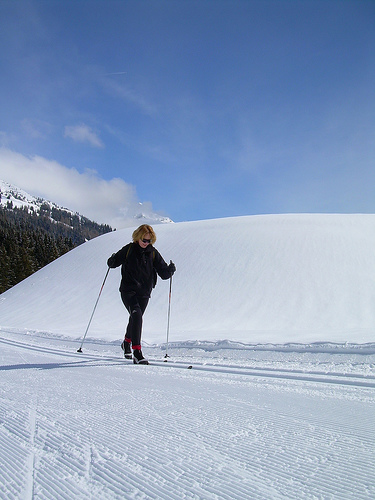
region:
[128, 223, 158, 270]
woman is wearing sunglasses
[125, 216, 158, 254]
woman is wearing sunglasses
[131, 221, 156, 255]
woman is wearing sunglasses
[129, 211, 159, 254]
woman is wearing sunglasses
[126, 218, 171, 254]
woman is wearing sunglasses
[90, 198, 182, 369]
woman skiing in white snow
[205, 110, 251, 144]
white clouds in blue sky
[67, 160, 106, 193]
white clouds in blue sky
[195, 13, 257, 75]
white clouds in blue sky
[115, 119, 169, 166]
white clouds in blue sky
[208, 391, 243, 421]
white snow on ground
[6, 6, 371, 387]
blue sky with thin and puffy clouds over mountains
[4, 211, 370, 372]
mound of smooth snow behind skier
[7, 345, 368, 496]
narrow ridges along ski path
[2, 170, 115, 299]
snow capping mountain covered with trees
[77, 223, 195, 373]
skier looking down at skis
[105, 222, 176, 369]
skier wearing dark outfit with red cuff at ankle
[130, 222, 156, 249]
woman with brown hair parted in middle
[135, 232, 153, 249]
dark sunglasses over face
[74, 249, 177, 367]
ski poles placed to the side of body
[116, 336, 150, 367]
black ski boots with white trim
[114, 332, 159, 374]
the shoes are black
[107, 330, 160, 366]
the shoes are black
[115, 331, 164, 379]
the shoes are black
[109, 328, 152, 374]
the shoes are black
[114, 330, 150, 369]
the shoes are black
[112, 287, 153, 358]
the pants are black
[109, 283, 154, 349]
the pants are black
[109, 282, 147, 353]
the pants are black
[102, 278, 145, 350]
the pants are black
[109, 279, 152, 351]
the pants are black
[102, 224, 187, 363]
A woman on skis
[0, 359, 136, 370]
The shadow of a woman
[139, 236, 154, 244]
A woman wearing dark shades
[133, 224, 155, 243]
A woman with blonde hair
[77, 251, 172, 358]
Two ski poles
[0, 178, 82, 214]
White snow on a mountain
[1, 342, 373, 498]
Lines in the snow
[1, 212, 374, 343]
A mountain of snow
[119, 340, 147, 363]
A woman wearing black shoes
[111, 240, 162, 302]
the jacket is black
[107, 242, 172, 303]
the jacket is black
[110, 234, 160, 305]
the jacket is black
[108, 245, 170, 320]
the jacket is black